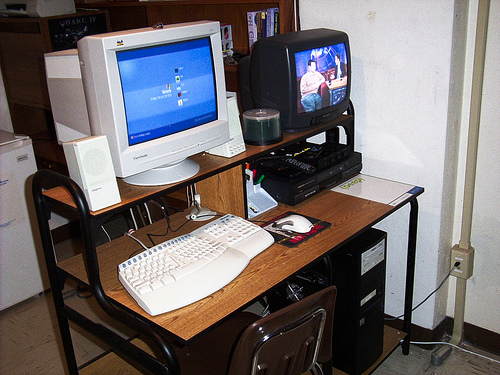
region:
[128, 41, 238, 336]
This is a computer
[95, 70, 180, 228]
The computer is old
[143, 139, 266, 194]
The computer is windows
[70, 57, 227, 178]
This is a monitor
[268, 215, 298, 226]
This is a mouse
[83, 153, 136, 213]
This is a speaker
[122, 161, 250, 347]
This is a keyboard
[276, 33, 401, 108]
This is a tv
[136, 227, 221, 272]
The keyboard is white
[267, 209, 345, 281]
The mouse is white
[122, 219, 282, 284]
A white computer keybord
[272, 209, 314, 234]
A white computer mouse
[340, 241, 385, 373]
A black computer CPU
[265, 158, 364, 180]
A black computer CPU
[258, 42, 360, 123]
A black computer monitor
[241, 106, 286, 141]
A clear CD holder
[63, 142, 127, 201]
A small white woofer speaker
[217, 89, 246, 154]
A small white woofer speaker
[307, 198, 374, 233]
A smooth brown table surface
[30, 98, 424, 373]
a wood and metal computer desk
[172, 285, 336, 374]
a brown chair at the desk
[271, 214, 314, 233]
a computer mouse on the desk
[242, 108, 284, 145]
a stack of digital media discs on the desk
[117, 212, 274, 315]
a white computer keyboard on the desk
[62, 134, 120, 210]
a white computer speaker on the desk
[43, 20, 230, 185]
a white computer monitor on the desk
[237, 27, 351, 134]
a small black TV on the desk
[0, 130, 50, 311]
a small white fridge in the background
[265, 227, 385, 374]
a large black PC tower under the desk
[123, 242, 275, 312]
key board on a desk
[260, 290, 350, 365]
chair next to desk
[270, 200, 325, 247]
mouse on a desk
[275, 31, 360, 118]
television on a desk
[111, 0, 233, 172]
monitor on desk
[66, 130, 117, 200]
speaker on a desk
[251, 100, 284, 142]
cds on a desk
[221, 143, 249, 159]
speaker on a desk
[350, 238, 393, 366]
computer on a desk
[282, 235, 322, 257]
mouse pad on a desk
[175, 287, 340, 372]
part of a brown chair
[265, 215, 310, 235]
a gray and white mouse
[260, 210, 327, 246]
a black and red mouse pad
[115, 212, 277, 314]
a white computer keyboard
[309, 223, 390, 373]
a black computer cpu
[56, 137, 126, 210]
a tall white computer speaker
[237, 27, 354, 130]
a small black t.v.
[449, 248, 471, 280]
a beige wall outlet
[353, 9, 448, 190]
part of a white wall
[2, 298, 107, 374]
part of a white tile floor